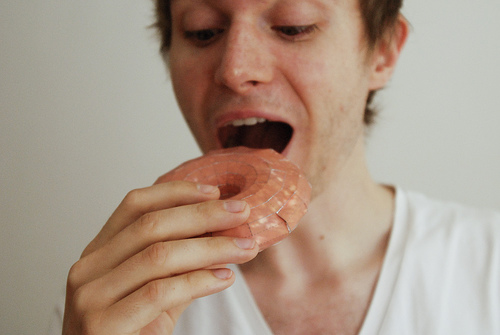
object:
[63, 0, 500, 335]
man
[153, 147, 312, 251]
donut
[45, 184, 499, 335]
shirt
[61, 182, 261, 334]
hand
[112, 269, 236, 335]
pinky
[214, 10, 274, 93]
nose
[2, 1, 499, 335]
wall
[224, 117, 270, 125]
teeth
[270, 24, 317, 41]
eyes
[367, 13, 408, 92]
ear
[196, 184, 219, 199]
nail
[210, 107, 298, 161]
mouth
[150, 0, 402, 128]
hair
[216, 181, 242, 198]
hole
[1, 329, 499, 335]
down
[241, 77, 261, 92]
nostrils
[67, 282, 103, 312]
knuckles